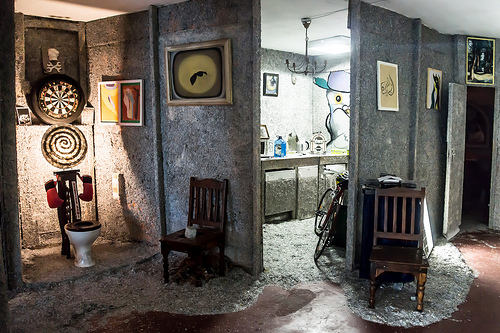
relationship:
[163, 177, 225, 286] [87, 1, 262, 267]
chair against wall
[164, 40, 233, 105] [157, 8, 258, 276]
picture on wall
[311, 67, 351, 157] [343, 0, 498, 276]
drawing on wall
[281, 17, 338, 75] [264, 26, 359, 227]
chandelier in kitchen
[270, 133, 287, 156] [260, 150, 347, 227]
bottle on table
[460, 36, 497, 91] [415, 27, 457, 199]
picture on wall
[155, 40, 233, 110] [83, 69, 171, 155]
picture on picture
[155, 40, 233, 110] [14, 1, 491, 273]
picture on wall